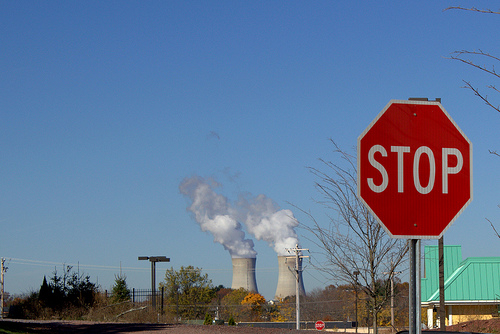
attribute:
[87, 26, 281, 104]
sky — blue , clear , cloudless 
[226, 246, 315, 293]
stacks — smoke, cement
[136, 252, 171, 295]
poles — metal, telephone, dark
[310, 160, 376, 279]
branches — bare, tree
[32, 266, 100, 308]
trees — pine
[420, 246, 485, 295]
roof — green, metal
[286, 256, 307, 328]
poles — wooden, telephone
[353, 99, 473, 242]
sign — stop, red , white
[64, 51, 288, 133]
sky — blue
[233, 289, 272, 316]
trees — some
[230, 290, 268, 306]
leaves — orange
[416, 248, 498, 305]
roof — green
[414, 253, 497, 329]
building — one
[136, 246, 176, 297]
light — one, street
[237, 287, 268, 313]
tree — distant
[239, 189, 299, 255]
smoke — white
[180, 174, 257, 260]
smoke — white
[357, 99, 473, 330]
sign — Red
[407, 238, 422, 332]
pole — silver 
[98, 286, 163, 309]
fence — Dark 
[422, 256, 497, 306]
roof — green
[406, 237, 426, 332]
pole — silver 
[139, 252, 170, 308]
light — Tall , black 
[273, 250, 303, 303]
building — grey, concrete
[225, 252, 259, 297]
building — grey, concrete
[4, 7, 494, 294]
sky — clear , blue